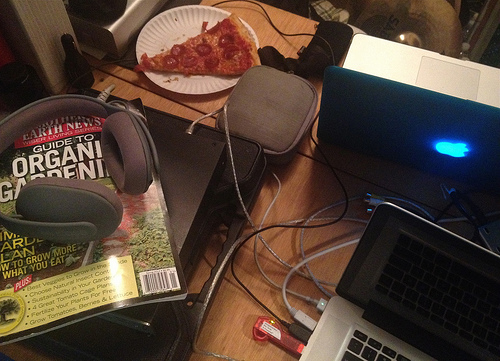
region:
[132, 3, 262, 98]
a pizza on a paper plate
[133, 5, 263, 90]
a slice of pizza on a paper plate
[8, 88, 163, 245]
a head phone on top of the magazine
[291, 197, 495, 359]
a laptop on the desk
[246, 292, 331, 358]
flash drive and cables connected to the laptop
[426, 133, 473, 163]
an apple logo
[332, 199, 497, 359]
a monitor of the laptop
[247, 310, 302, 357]
a red flash drive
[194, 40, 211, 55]
a pepperoni topping on a pizza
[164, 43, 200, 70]
pepperoni on the pizza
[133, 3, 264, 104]
slice of pizza on a paper plate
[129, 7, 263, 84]
slice of pepperoni pizza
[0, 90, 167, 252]
large over the ear headset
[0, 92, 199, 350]
edition of Mother Earth News magaizine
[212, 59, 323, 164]
small grey compact disc wallet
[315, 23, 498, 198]
an apple laptop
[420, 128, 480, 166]
the apple logo, lit up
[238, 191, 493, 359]
laptop with several devices plugged in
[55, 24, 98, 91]
car charging adapter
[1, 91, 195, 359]
magazine about organic gardening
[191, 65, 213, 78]
part of a pizza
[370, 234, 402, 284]
part of a board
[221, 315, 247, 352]
part of a table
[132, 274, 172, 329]
edge of a book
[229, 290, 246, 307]
part of a table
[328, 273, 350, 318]
edge of a keyboard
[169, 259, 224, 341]
edge of a book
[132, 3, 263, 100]
Slice of pepperoni pizza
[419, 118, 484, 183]
Apple brand logo in blue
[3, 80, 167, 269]
Over the ear headphones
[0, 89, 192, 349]
Guide to Organic Gardening Magazine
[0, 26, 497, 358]
Messy college dorm room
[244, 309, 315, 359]
USB Removable storage device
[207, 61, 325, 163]
Portable electronic carrying case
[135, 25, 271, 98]
Disposable white paper plate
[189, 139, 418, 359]
Tangled computer cable and internet wires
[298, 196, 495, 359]
laptop computer powered off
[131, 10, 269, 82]
slice of pizza on plate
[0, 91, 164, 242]
headphones above the magazine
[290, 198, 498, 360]
laptop on the table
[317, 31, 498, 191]
apple laptop on the table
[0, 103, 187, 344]
magazine under the headphones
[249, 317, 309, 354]
USB connected to laptop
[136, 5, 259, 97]
white plate on the table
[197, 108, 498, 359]
white, grey and black cable next to laptops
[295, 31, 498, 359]
two taptops on the desk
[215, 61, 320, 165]
grey CD holder next to laptop